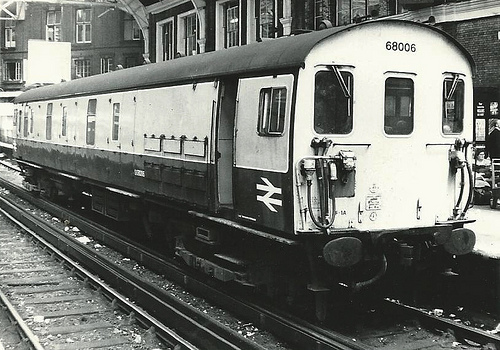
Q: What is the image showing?
A: It is showing a station.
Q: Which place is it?
A: It is a station.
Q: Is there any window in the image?
A: Yes, there is a window.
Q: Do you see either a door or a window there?
A: Yes, there is a window.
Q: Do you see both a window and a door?
A: Yes, there are both a window and a door.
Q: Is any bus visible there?
A: No, there are no buses.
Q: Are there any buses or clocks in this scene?
A: No, there are no buses or clocks.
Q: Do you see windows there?
A: Yes, there is a window.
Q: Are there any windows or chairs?
A: Yes, there is a window.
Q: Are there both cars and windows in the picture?
A: Yes, there are both a window and a car.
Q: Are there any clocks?
A: No, there are no clocks.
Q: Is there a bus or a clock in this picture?
A: No, there are no clocks or buses.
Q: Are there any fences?
A: No, there are no fences.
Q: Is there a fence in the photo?
A: No, there are no fences.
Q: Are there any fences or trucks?
A: No, there are no fences or trucks.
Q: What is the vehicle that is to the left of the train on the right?
A: The vehicle is a car.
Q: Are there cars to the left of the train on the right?
A: Yes, there is a car to the left of the train.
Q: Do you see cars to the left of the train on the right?
A: Yes, there is a car to the left of the train.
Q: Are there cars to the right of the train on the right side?
A: No, the car is to the left of the train.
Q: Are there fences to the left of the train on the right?
A: No, there is a car to the left of the train.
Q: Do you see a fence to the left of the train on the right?
A: No, there is a car to the left of the train.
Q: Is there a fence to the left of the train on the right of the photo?
A: No, there is a car to the left of the train.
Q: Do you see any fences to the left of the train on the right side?
A: No, there is a car to the left of the train.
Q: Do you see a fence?
A: No, there are no fences.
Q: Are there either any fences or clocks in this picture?
A: No, there are no fences or clocks.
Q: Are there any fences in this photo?
A: No, there are no fences.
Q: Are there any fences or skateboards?
A: No, there are no fences or skateboards.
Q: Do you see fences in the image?
A: No, there are no fences.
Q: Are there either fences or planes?
A: No, there are no fences or planes.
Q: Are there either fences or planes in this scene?
A: No, there are no fences or planes.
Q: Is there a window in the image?
A: Yes, there is a window.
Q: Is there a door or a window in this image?
A: Yes, there is a window.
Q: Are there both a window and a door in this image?
A: Yes, there are both a window and a door.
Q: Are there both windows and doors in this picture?
A: Yes, there are both a window and a door.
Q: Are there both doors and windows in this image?
A: Yes, there are both a window and a door.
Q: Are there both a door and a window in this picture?
A: Yes, there are both a window and a door.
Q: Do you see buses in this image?
A: No, there are no buses.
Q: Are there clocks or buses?
A: No, there are no buses or clocks.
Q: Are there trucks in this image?
A: No, there are no trucks.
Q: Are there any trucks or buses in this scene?
A: No, there are no trucks or buses.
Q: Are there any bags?
A: No, there are no bags.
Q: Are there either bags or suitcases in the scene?
A: No, there are no bags or suitcases.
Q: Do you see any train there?
A: Yes, there is a train.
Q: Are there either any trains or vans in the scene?
A: Yes, there is a train.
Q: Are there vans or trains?
A: Yes, there is a train.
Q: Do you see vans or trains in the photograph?
A: Yes, there is a train.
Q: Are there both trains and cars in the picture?
A: Yes, there are both a train and a car.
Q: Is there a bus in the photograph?
A: No, there are no buses.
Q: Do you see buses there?
A: No, there are no buses.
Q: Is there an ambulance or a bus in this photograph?
A: No, there are no buses or ambulances.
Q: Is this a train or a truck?
A: This is a train.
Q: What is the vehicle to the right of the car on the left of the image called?
A: The vehicle is a train.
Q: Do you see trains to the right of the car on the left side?
A: Yes, there is a train to the right of the car.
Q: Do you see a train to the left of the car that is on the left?
A: No, the train is to the right of the car.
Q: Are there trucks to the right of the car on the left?
A: No, there is a train to the right of the car.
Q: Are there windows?
A: Yes, there is a window.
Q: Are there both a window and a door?
A: Yes, there are both a window and a door.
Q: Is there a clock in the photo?
A: No, there are no clocks.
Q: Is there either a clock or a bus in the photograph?
A: No, there are no clocks or buses.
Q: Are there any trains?
A: Yes, there is a train.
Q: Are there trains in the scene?
A: Yes, there is a train.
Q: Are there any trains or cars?
A: Yes, there is a train.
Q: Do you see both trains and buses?
A: No, there is a train but no buses.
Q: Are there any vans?
A: No, there are no vans.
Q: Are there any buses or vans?
A: No, there are no vans or buses.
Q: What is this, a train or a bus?
A: This is a train.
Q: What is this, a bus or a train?
A: This is a train.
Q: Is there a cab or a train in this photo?
A: Yes, there is a train.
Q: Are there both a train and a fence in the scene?
A: No, there is a train but no fences.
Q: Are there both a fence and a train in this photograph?
A: No, there is a train but no fences.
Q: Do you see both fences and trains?
A: No, there is a train but no fences.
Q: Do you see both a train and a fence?
A: No, there is a train but no fences.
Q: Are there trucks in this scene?
A: No, there are no trucks.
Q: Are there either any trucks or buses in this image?
A: No, there are no trucks or buses.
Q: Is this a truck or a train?
A: This is a train.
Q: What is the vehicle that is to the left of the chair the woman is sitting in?
A: The vehicle is a train.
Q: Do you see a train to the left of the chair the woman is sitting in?
A: Yes, there is a train to the left of the chair.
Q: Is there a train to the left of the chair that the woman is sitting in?
A: Yes, there is a train to the left of the chair.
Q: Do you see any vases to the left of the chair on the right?
A: No, there is a train to the left of the chair.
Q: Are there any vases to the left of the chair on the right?
A: No, there is a train to the left of the chair.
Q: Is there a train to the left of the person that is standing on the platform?
A: Yes, there is a train to the left of the person.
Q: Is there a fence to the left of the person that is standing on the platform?
A: No, there is a train to the left of the person.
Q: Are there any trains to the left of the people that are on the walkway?
A: Yes, there is a train to the left of the people.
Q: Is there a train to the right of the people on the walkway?
A: No, the train is to the left of the people.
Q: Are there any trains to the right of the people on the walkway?
A: No, the train is to the left of the people.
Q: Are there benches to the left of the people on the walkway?
A: No, there is a train to the left of the people.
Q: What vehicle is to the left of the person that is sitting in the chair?
A: The vehicle is a train.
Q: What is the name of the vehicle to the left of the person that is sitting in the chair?
A: The vehicle is a train.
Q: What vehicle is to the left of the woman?
A: The vehicle is a train.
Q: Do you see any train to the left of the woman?
A: Yes, there is a train to the left of the woman.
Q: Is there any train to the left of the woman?
A: Yes, there is a train to the left of the woman.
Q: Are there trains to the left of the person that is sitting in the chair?
A: Yes, there is a train to the left of the woman.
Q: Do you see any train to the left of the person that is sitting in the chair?
A: Yes, there is a train to the left of the woman.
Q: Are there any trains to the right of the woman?
A: No, the train is to the left of the woman.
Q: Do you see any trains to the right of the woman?
A: No, the train is to the left of the woman.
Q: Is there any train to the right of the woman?
A: No, the train is to the left of the woman.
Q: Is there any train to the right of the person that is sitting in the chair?
A: No, the train is to the left of the woman.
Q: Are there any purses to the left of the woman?
A: No, there is a train to the left of the woman.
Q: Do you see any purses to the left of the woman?
A: No, there is a train to the left of the woman.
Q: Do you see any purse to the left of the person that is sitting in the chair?
A: No, there is a train to the left of the woman.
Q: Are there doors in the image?
A: Yes, there is a door.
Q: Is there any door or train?
A: Yes, there is a door.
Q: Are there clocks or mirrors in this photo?
A: No, there are no mirrors or clocks.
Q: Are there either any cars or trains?
A: Yes, there is a train.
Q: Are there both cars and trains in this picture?
A: Yes, there are both a train and cars.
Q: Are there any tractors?
A: No, there are no tractors.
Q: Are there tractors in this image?
A: No, there are no tractors.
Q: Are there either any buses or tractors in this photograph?
A: No, there are no tractors or buses.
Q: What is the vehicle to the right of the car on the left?
A: The vehicle is a train.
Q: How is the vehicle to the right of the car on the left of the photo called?
A: The vehicle is a train.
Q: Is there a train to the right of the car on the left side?
A: Yes, there is a train to the right of the car.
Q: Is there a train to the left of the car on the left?
A: No, the train is to the right of the car.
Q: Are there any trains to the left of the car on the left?
A: No, the train is to the right of the car.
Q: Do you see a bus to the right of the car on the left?
A: No, there is a train to the right of the car.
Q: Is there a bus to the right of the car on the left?
A: No, there is a train to the right of the car.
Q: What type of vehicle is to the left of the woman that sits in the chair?
A: The vehicle is a train.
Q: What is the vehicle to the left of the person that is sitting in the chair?
A: The vehicle is a train.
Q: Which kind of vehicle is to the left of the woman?
A: The vehicle is a train.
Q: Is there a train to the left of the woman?
A: Yes, there is a train to the left of the woman.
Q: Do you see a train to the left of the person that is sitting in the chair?
A: Yes, there is a train to the left of the woman.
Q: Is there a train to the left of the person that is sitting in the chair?
A: Yes, there is a train to the left of the woman.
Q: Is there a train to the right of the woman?
A: No, the train is to the left of the woman.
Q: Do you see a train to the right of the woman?
A: No, the train is to the left of the woman.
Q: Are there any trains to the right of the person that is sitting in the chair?
A: No, the train is to the left of the woman.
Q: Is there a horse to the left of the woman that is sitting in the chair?
A: No, there is a train to the left of the woman.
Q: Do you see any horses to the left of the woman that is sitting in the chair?
A: No, there is a train to the left of the woman.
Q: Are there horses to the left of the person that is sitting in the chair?
A: No, there is a train to the left of the woman.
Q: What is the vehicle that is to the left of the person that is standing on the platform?
A: The vehicle is a train.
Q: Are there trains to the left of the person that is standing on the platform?
A: Yes, there is a train to the left of the person.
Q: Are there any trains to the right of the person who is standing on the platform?
A: No, the train is to the left of the person.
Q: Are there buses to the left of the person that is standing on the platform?
A: No, there is a train to the left of the person.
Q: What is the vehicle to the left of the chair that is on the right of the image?
A: The vehicle is a train.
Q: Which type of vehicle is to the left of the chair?
A: The vehicle is a train.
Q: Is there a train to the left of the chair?
A: Yes, there is a train to the left of the chair.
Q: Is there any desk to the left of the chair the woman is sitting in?
A: No, there is a train to the left of the chair.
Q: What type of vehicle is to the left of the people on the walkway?
A: The vehicle is a train.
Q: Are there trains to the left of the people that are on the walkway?
A: Yes, there is a train to the left of the people.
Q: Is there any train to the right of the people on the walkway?
A: No, the train is to the left of the people.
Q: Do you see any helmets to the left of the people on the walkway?
A: No, there is a train to the left of the people.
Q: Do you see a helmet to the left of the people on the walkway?
A: No, there is a train to the left of the people.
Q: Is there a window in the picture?
A: Yes, there is a window.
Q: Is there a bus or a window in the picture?
A: Yes, there is a window.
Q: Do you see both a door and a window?
A: Yes, there are both a window and a door.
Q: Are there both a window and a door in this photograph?
A: Yes, there are both a window and a door.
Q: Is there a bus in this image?
A: No, there are no buses.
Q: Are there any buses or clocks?
A: No, there are no buses or clocks.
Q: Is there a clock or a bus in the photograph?
A: No, there are no buses or clocks.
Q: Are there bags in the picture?
A: No, there are no bags.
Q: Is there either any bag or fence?
A: No, there are no bags or fences.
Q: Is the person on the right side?
A: Yes, the person is on the right of the image.